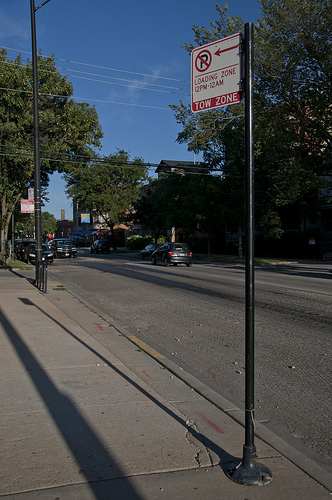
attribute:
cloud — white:
[103, 62, 168, 110]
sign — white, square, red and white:
[191, 32, 243, 114]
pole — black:
[242, 18, 263, 465]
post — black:
[186, 19, 267, 406]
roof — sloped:
[155, 158, 208, 172]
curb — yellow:
[92, 314, 155, 371]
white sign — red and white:
[192, 32, 240, 112]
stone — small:
[288, 363, 296, 369]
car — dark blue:
[148, 239, 195, 269]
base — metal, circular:
[224, 453, 272, 486]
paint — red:
[95, 319, 233, 448]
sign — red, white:
[177, 39, 254, 122]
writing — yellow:
[122, 329, 170, 364]